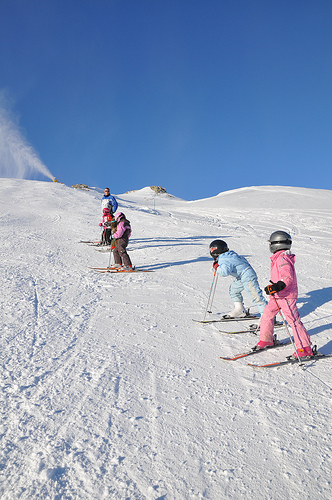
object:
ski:
[247, 354, 331, 368]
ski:
[220, 342, 285, 361]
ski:
[219, 324, 288, 335]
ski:
[192, 317, 261, 323]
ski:
[94, 270, 156, 273]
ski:
[88, 266, 122, 270]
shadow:
[135, 256, 252, 273]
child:
[109, 211, 135, 271]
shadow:
[278, 322, 331, 358]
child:
[250, 230, 313, 361]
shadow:
[281, 287, 332, 327]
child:
[209, 240, 276, 326]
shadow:
[126, 243, 208, 251]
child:
[99, 208, 116, 245]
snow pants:
[259, 296, 311, 347]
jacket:
[270, 250, 299, 299]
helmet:
[269, 231, 292, 253]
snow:
[0, 93, 55, 183]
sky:
[1, 0, 330, 177]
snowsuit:
[217, 250, 276, 320]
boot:
[285, 346, 313, 360]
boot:
[251, 343, 272, 352]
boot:
[223, 302, 247, 319]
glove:
[264, 281, 286, 296]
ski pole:
[271, 289, 305, 370]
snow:
[0, 180, 332, 499]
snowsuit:
[260, 249, 313, 349]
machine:
[53, 178, 58, 183]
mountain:
[0, 179, 330, 500]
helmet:
[209, 239, 229, 257]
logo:
[210, 246, 218, 253]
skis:
[219, 339, 331, 368]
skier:
[101, 187, 118, 236]